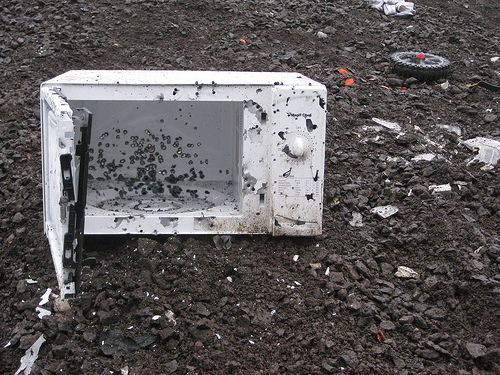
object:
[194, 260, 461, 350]
ground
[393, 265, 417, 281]
rock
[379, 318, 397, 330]
rock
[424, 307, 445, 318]
rock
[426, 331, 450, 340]
rock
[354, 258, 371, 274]
rock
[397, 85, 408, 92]
something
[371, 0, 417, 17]
cloth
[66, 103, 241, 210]
inside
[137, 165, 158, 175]
holes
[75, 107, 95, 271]
part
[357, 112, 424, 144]
rock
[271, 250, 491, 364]
dirt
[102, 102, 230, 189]
wall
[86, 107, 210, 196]
bullet holes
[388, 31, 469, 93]
tire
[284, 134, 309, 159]
knob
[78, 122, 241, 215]
dial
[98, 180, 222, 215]
glass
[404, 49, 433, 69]
spot wheel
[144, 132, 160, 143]
holes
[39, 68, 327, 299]
microwave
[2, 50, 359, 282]
lawnmower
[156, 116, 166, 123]
marks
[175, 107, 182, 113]
marks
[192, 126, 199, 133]
marks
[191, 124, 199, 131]
marks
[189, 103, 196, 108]
marks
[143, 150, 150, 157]
particle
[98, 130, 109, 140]
particle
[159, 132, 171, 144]
particle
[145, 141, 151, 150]
particle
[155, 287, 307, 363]
rocks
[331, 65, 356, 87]
pieces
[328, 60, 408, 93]
particles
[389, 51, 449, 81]
object/ground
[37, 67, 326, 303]
object/ground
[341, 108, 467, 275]
rocks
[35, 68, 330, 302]
plastic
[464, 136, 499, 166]
plastic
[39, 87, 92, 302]
door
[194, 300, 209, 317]
rock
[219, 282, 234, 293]
rock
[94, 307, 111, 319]
rock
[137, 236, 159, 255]
rock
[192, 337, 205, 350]
rock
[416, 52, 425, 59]
spot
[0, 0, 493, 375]
dump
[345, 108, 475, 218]
particles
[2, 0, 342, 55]
ground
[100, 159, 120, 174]
holes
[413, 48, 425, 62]
red center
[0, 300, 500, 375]
dirt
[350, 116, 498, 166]
pieces